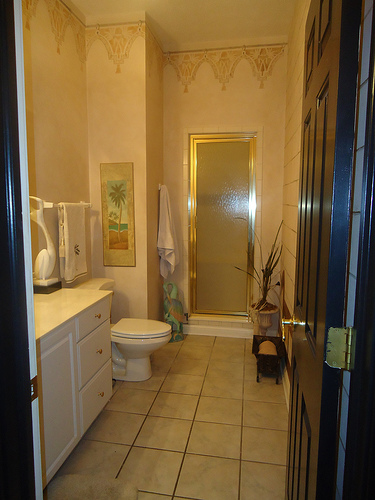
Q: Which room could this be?
A: It is a bathroom.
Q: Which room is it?
A: It is a bathroom.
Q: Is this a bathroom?
A: Yes, it is a bathroom.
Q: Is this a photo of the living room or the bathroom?
A: It is showing the bathroom.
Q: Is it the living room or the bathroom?
A: It is the bathroom.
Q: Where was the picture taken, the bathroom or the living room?
A: It was taken at the bathroom.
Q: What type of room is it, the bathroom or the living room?
A: It is the bathroom.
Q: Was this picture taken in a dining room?
A: No, the picture was taken in a bathroom.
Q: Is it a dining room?
A: No, it is a bathroom.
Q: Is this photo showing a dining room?
A: No, the picture is showing a bathroom.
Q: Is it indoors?
A: Yes, it is indoors.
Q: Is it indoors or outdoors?
A: It is indoors.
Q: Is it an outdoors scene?
A: No, it is indoors.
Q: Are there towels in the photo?
A: Yes, there is a towel.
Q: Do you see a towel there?
A: Yes, there is a towel.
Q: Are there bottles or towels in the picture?
A: Yes, there is a towel.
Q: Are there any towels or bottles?
A: Yes, there is a towel.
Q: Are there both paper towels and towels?
A: No, there is a towel but no paper towels.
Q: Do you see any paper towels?
A: No, there are no paper towels.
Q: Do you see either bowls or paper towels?
A: No, there are no paper towels or bowls.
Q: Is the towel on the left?
A: Yes, the towel is on the left of the image.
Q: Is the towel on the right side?
A: No, the towel is on the left of the image.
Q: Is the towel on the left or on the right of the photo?
A: The towel is on the left of the image.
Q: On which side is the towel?
A: The towel is on the left of the image.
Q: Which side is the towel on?
A: The towel is on the left of the image.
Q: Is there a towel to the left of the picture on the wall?
A: Yes, there is a towel to the left of the picture.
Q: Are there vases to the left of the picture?
A: No, there is a towel to the left of the picture.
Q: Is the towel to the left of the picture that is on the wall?
A: Yes, the towel is to the left of the picture.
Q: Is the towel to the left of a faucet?
A: No, the towel is to the left of the picture.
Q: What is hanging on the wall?
A: The towel is hanging on the wall.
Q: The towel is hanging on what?
A: The towel is hanging on the wall.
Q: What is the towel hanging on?
A: The towel is hanging on the wall.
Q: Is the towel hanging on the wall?
A: Yes, the towel is hanging on the wall.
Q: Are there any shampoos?
A: No, there are no shampoos.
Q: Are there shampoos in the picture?
A: No, there are no shampoos.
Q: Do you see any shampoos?
A: No, there are no shampoos.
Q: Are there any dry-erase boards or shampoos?
A: No, there are no shampoos or dry-erase boards.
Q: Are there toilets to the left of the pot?
A: Yes, there is a toilet to the left of the pot.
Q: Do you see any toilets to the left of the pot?
A: Yes, there is a toilet to the left of the pot.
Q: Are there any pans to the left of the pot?
A: No, there is a toilet to the left of the pot.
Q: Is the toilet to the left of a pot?
A: Yes, the toilet is to the left of a pot.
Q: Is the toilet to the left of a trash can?
A: No, the toilet is to the left of a pot.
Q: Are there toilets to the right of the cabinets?
A: Yes, there is a toilet to the right of the cabinets.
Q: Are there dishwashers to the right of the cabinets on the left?
A: No, there is a toilet to the right of the cabinets.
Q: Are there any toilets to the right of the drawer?
A: Yes, there is a toilet to the right of the drawer.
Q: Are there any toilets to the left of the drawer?
A: No, the toilet is to the right of the drawer.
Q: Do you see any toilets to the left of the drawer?
A: No, the toilet is to the right of the drawer.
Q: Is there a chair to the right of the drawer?
A: No, there is a toilet to the right of the drawer.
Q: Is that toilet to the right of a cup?
A: No, the toilet is to the right of a drawer.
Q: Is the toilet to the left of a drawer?
A: No, the toilet is to the right of a drawer.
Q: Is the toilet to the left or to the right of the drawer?
A: The toilet is to the right of the drawer.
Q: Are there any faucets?
A: No, there are no faucets.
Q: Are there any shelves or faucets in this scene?
A: No, there are no faucets or shelves.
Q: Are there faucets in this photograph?
A: No, there are no faucets.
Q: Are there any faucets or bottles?
A: No, there are no faucets or bottles.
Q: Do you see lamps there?
A: No, there are no lamps.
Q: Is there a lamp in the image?
A: No, there are no lamps.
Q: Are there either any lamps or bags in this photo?
A: No, there are no lamps or bags.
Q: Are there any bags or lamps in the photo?
A: No, there are no lamps or bags.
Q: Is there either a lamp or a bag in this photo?
A: No, there are no lamps or bags.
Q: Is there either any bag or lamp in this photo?
A: No, there are no lamps or bags.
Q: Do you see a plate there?
A: No, there are no plates.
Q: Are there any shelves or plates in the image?
A: No, there are no plates or shelves.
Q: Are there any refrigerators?
A: No, there are no refrigerators.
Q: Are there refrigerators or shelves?
A: No, there are no refrigerators or shelves.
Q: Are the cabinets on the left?
A: Yes, the cabinets are on the left of the image.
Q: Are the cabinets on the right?
A: No, the cabinets are on the left of the image.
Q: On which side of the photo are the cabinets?
A: The cabinets are on the left of the image.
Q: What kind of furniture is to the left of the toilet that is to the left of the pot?
A: The pieces of furniture are cabinets.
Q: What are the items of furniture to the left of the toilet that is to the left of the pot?
A: The pieces of furniture are cabinets.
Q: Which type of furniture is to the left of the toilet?
A: The pieces of furniture are cabinets.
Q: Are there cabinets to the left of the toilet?
A: Yes, there are cabinets to the left of the toilet.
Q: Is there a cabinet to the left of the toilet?
A: Yes, there are cabinets to the left of the toilet.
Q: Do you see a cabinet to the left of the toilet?
A: Yes, there are cabinets to the left of the toilet.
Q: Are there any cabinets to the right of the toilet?
A: No, the cabinets are to the left of the toilet.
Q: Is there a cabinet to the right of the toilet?
A: No, the cabinets are to the left of the toilet.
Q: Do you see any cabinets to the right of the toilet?
A: No, the cabinets are to the left of the toilet.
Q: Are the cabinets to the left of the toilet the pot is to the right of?
A: Yes, the cabinets are to the left of the toilet.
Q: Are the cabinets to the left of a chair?
A: No, the cabinets are to the left of the toilet.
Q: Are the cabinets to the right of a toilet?
A: No, the cabinets are to the left of a toilet.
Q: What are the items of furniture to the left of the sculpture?
A: The pieces of furniture are cabinets.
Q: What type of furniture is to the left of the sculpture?
A: The pieces of furniture are cabinets.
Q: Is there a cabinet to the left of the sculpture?
A: Yes, there are cabinets to the left of the sculpture.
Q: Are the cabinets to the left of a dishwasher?
A: No, the cabinets are to the left of the sculpture.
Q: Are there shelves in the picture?
A: No, there are no shelves.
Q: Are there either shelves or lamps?
A: No, there are no shelves or lamps.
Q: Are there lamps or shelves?
A: No, there are no shelves or lamps.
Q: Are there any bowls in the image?
A: No, there are no bowls.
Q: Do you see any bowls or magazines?
A: No, there are no bowls or magazines.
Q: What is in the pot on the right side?
A: The plant is in the pot.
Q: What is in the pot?
A: The plant is in the pot.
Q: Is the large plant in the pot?
A: Yes, the plant is in the pot.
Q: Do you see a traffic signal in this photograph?
A: No, there are no traffic lights.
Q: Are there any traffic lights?
A: No, there are no traffic lights.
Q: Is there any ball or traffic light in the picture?
A: No, there are no traffic lights or balls.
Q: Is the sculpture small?
A: Yes, the sculpture is small.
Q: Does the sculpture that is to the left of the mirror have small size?
A: Yes, the sculpture is small.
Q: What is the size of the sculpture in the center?
A: The sculpture is small.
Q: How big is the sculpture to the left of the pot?
A: The sculpture is small.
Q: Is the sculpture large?
A: No, the sculpture is small.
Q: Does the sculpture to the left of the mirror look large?
A: No, the sculpture is small.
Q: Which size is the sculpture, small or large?
A: The sculpture is small.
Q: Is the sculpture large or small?
A: The sculpture is small.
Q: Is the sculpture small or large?
A: The sculpture is small.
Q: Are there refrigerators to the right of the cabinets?
A: No, there is a sculpture to the right of the cabinets.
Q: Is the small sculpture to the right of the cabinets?
A: Yes, the sculpture is to the right of the cabinets.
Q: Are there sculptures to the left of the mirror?
A: Yes, there is a sculpture to the left of the mirror.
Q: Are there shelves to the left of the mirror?
A: No, there is a sculpture to the left of the mirror.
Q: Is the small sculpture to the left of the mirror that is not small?
A: Yes, the sculpture is to the left of the mirror.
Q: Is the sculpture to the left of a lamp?
A: No, the sculpture is to the left of the mirror.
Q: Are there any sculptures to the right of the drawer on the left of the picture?
A: Yes, there is a sculpture to the right of the drawer.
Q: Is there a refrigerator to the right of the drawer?
A: No, there is a sculpture to the right of the drawer.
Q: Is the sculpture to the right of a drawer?
A: Yes, the sculpture is to the right of a drawer.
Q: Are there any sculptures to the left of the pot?
A: Yes, there is a sculpture to the left of the pot.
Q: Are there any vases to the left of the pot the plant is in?
A: No, there is a sculpture to the left of the pot.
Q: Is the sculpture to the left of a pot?
A: Yes, the sculpture is to the left of a pot.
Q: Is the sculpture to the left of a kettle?
A: No, the sculpture is to the left of a pot.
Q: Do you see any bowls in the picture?
A: No, there are no bowls.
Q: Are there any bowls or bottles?
A: No, there are no bowls or bottles.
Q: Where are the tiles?
A: The tiles are on the floor.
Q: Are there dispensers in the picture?
A: No, there are no dispensers.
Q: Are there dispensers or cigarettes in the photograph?
A: No, there are no dispensers or cigarettes.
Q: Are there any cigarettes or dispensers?
A: No, there are no dispensers or cigarettes.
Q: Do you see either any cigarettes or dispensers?
A: No, there are no dispensers or cigarettes.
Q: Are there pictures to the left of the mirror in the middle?
A: Yes, there is a picture to the left of the mirror.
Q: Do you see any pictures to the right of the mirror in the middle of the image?
A: No, the picture is to the left of the mirror.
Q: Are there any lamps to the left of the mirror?
A: No, there is a picture to the left of the mirror.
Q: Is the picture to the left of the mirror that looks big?
A: Yes, the picture is to the left of the mirror.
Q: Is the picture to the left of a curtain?
A: No, the picture is to the left of the mirror.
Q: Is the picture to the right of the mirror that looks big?
A: No, the picture is to the left of the mirror.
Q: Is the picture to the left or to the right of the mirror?
A: The picture is to the left of the mirror.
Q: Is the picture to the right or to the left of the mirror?
A: The picture is to the left of the mirror.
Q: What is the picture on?
A: The picture is on the wall.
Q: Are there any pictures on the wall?
A: Yes, there is a picture on the wall.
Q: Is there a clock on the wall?
A: No, there is a picture on the wall.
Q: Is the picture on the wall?
A: Yes, the picture is on the wall.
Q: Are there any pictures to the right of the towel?
A: Yes, there is a picture to the right of the towel.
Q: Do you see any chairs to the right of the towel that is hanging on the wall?
A: No, there is a picture to the right of the towel.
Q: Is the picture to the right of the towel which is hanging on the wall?
A: Yes, the picture is to the right of the towel.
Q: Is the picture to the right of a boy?
A: No, the picture is to the right of the towel.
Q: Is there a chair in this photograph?
A: No, there are no chairs.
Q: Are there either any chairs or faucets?
A: No, there are no chairs or faucets.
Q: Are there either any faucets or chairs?
A: No, there are no chairs or faucets.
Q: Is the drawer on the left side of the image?
A: Yes, the drawer is on the left of the image.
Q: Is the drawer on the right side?
A: No, the drawer is on the left of the image.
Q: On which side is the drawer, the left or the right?
A: The drawer is on the left of the image.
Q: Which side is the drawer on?
A: The drawer is on the left of the image.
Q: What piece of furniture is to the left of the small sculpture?
A: The piece of furniture is a drawer.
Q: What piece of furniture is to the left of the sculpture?
A: The piece of furniture is a drawer.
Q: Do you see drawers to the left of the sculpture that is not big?
A: Yes, there is a drawer to the left of the sculpture.